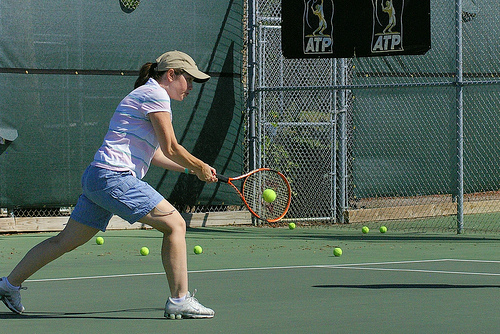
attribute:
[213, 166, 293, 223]
tennis racket — red, orange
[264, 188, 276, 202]
tennis ball — green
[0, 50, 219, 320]
woman — tennis player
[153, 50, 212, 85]
baseball hat — tan, brown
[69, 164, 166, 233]
shorts — denim, blue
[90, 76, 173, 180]
shirt — short sleeved, striped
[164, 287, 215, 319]
shoe — white, gray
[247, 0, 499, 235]
fence — gray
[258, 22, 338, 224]
gate — metal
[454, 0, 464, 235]
pole — metal